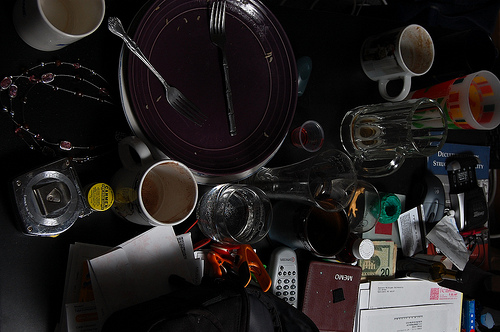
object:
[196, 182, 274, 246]
glass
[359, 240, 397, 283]
dollar bill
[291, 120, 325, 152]
shot glass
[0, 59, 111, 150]
jewelry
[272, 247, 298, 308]
control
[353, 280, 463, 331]
mail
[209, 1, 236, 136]
fork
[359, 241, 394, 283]
$20 bill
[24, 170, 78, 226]
tape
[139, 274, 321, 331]
bag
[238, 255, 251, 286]
zip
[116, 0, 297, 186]
plate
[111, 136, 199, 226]
cup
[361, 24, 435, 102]
cup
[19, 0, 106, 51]
cup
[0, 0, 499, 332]
table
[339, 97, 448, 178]
glass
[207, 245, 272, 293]
clips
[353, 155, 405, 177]
handle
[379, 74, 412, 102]
handle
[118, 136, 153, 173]
handle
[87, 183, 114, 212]
carmex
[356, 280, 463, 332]
printed papers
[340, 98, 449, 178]
dishes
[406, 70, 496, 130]
cup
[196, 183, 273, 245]
cup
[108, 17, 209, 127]
fork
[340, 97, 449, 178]
beer mug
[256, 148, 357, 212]
glass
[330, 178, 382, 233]
glass